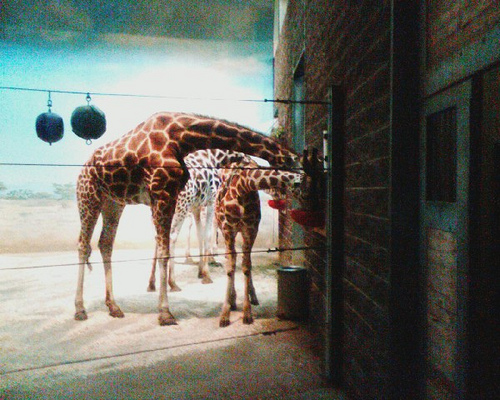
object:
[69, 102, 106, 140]
object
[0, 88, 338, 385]
fence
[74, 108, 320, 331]
giraffe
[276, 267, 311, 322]
container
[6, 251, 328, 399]
ground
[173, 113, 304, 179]
neck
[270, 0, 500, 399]
building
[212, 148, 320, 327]
giraffe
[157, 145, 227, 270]
giraffe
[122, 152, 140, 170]
spots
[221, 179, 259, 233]
spots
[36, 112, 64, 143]
container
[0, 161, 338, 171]
wire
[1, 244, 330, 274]
wire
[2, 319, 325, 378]
wire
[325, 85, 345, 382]
pole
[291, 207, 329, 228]
tray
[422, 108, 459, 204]
window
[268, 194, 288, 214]
bin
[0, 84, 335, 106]
line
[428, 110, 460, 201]
bars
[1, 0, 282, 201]
sky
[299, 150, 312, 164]
horns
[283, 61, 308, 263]
door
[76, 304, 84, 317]
feet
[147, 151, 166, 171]
spot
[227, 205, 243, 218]
spot